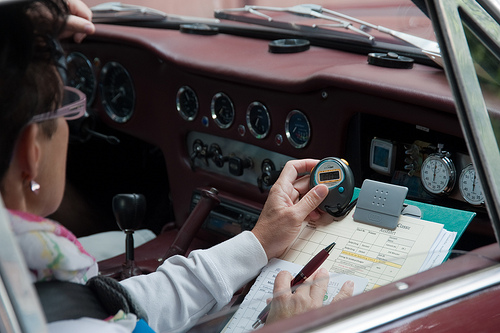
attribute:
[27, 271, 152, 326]
seat belt — grey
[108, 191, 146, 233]
rubber ball — LEATHER 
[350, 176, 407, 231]
clip — grey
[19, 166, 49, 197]
earring — small, shiny, silver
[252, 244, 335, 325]
pen — red  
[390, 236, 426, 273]
paper — WHITE  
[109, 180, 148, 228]
top — black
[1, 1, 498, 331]
scene — inside 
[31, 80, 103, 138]
glasses — framed, light pink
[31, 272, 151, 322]
seat belt — gray 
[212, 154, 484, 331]
clipboard — green 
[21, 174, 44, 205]
earring — silver 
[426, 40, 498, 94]
crome — SILVER 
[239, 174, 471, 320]
paper — white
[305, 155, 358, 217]
stopwatch — grey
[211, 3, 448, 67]
windshield wiper — chrome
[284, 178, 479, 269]
clipboard — green, grey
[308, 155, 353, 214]
stopwatch — yellow, teal, grey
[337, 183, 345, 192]
button — blue, small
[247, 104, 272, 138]
gauge — round 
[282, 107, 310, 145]
gauge — round 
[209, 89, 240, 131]
gauge — round 